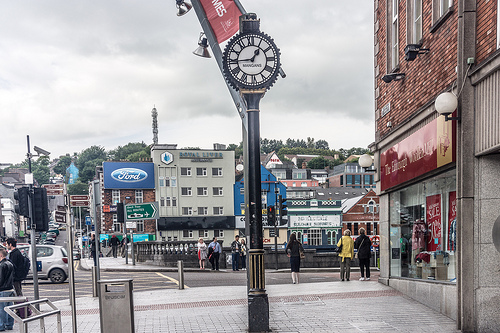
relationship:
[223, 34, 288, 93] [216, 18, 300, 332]
clock on pole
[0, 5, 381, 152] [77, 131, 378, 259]
sky above buildings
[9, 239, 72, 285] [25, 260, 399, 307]
car on street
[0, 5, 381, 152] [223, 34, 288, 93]
sky above clock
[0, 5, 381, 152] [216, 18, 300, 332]
sky above pole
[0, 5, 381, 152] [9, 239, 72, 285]
sky above car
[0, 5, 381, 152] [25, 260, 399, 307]
sky above street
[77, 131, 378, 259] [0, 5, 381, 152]
buildings under sky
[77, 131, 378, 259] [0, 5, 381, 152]
buildings below sky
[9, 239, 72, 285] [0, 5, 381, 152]
car below sky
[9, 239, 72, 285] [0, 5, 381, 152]
car under sky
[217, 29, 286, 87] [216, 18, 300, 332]
clock on pole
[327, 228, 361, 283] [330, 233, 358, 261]
person with jacket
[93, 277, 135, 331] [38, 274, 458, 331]
trash container on sidewalk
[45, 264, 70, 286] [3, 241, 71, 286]
wheel on vehicle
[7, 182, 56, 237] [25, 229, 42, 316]
signal on pole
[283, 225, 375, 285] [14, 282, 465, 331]
people standing on sidewalk